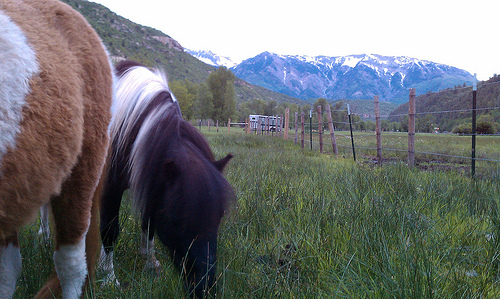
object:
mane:
[106, 59, 187, 225]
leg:
[44, 164, 105, 299]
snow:
[181, 47, 239, 70]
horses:
[1, 0, 120, 299]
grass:
[0, 131, 499, 298]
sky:
[94, 1, 499, 86]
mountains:
[223, 48, 482, 109]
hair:
[104, 58, 185, 239]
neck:
[123, 87, 187, 188]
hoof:
[142, 257, 162, 270]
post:
[470, 72, 477, 175]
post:
[404, 87, 416, 166]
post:
[282, 104, 288, 141]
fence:
[197, 72, 500, 183]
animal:
[97, 54, 235, 299]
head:
[151, 151, 238, 298]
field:
[0, 128, 499, 298]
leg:
[91, 185, 123, 279]